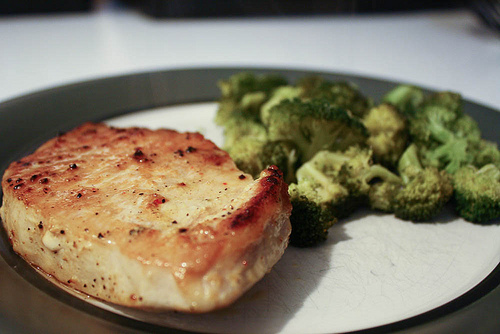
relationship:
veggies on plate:
[229, 68, 326, 150] [338, 227, 489, 321]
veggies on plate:
[342, 84, 418, 152] [338, 227, 489, 321]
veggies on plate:
[296, 142, 367, 232] [338, 227, 489, 321]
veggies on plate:
[387, 151, 495, 224] [338, 227, 489, 321]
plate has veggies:
[338, 227, 489, 321] [229, 68, 326, 150]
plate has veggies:
[338, 227, 489, 321] [342, 84, 418, 152]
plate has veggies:
[338, 227, 489, 321] [296, 142, 367, 232]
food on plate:
[58, 72, 477, 287] [338, 227, 489, 321]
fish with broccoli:
[32, 124, 271, 311] [269, 98, 361, 157]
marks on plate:
[317, 244, 359, 289] [338, 227, 489, 321]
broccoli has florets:
[269, 98, 361, 157] [304, 96, 335, 119]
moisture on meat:
[128, 244, 215, 280] [153, 163, 237, 293]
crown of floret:
[293, 193, 328, 249] [287, 183, 313, 226]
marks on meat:
[227, 164, 288, 214] [153, 163, 237, 293]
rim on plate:
[453, 291, 492, 328] [338, 227, 489, 321]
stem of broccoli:
[296, 129, 336, 159] [269, 98, 361, 157]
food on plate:
[252, 72, 479, 239] [338, 227, 489, 321]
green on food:
[322, 108, 396, 165] [252, 72, 479, 239]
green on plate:
[322, 108, 396, 165] [338, 227, 489, 321]